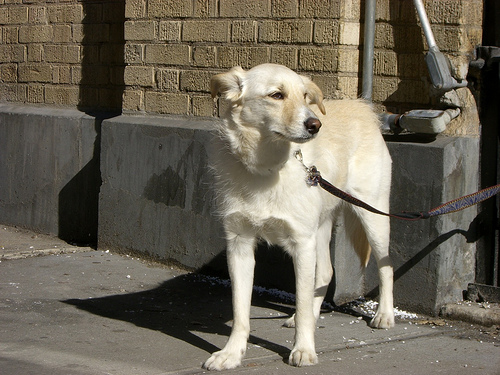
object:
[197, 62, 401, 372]
dog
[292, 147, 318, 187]
clasp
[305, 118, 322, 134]
nose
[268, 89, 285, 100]
right eye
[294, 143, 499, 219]
leash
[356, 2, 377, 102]
pole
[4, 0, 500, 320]
building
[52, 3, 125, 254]
shadow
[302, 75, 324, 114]
left ear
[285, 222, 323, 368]
front left leg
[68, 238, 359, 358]
shadow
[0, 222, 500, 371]
pavement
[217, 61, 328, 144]
head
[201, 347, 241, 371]
paw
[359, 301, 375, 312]
pellets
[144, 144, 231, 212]
stain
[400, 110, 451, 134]
box